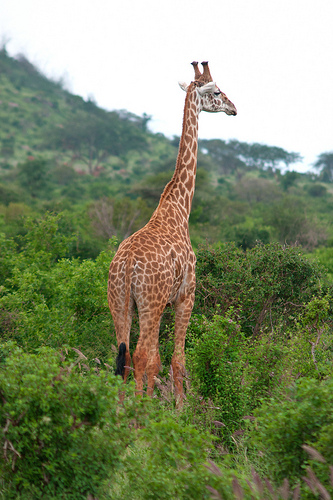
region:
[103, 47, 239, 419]
a giraffe standing tall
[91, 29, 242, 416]
a giraffe standing in the weeds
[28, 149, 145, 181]
animals under a large tree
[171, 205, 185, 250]
the giraffe has spots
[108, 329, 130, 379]
the tail has black hair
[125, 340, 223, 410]
the green weeds are half way up the giraffes legs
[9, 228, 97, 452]
lots of green vegetation grows here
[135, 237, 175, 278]
the giraffe is two different colors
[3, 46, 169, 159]
hilly terrain in the background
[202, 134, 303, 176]
a row of trees on the hill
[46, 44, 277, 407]
a giraffe in a field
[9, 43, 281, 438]
a giraffe in tall grass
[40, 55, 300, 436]
a giraffe in bushes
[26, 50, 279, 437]
giraffe walking in a field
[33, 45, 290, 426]
giraffe walking in bushes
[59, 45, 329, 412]
giraffe walking on tall grass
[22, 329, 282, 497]
a field of bushes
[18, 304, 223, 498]
an area of bushes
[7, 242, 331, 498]
an area with bushes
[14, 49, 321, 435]
an area with giraffe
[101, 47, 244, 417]
brown and white giraffe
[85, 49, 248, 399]
giraffe with brown spots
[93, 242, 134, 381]
giraffe long tail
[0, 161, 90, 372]
green forest colored landscape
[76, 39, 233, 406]
giraffe looking around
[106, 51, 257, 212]
giraffe with a long neck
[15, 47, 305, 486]
giraffe in the wild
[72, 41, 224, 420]
giraffe standing tall on the ground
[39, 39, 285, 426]
giraffe looking at trees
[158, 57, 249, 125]
two horns on giraffe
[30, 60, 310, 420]
The giraffe is among the bushes.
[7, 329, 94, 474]
The bushes are green.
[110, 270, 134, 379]
The giraffe has a tail.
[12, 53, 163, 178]
A hill in the distance.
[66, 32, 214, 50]
The sky is overcast.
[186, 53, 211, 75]
Two horns on the giraffe's head.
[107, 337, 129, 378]
The hair on the end of the giraffe's tail is black.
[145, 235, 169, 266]
The giraffe has brown spots.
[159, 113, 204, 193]
The giraffe has a skinny neck.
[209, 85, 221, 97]
An eye on the giraffe.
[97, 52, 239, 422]
Giraffe standing in the wild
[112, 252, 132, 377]
Tail of a giraffe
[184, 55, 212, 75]
Ossicones (horns) of the giraffe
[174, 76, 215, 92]
Giraffe ears which are white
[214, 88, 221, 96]
Slightly open giraffe eye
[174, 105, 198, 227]
Long neck of giraffe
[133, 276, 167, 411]
Long leg of giraffe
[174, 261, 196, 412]
Long leg of giraffe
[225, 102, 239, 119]
The mouth of giraffe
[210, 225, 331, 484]
Lush green shrubs